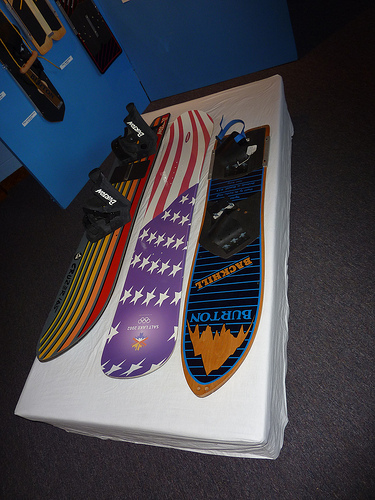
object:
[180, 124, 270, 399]
snowboard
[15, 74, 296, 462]
table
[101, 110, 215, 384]
snowboard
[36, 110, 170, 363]
snowboard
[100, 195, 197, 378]
stars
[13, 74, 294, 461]
cloth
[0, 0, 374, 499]
carpet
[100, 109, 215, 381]
flag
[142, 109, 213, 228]
stripes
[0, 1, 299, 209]
wall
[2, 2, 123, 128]
snowboards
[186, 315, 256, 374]
decal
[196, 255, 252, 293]
word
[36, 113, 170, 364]
lines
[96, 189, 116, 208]
word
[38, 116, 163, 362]
stripe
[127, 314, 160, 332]
symbol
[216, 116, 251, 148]
footstrap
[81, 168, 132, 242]
black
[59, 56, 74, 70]
sign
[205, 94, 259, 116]
wrinkles